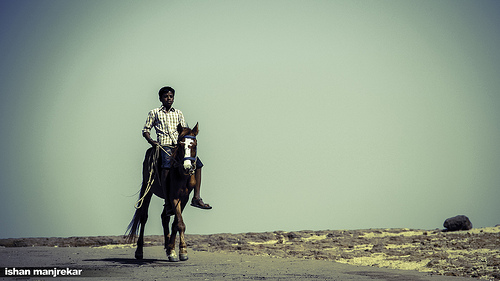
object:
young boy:
[143, 87, 211, 212]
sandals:
[190, 195, 213, 209]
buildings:
[123, 121, 199, 262]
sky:
[327, 53, 431, 130]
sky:
[0, 4, 499, 169]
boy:
[140, 85, 212, 210]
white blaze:
[183, 137, 193, 166]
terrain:
[0, 227, 500, 278]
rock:
[442, 214, 472, 231]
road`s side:
[6, 221, 497, 279]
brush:
[97, 220, 493, 280]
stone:
[442, 212, 473, 231]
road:
[2, 244, 500, 281]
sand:
[340, 228, 447, 258]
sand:
[440, 232, 472, 269]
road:
[341, 235, 415, 253]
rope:
[134, 142, 165, 211]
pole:
[140, 122, 206, 197]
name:
[3, 266, 85, 278]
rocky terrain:
[200, 225, 500, 268]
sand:
[318, 238, 491, 273]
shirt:
[141, 108, 188, 147]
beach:
[0, 227, 499, 280]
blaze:
[182, 136, 192, 168]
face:
[174, 121, 200, 175]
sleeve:
[143, 107, 158, 133]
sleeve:
[176, 111, 186, 128]